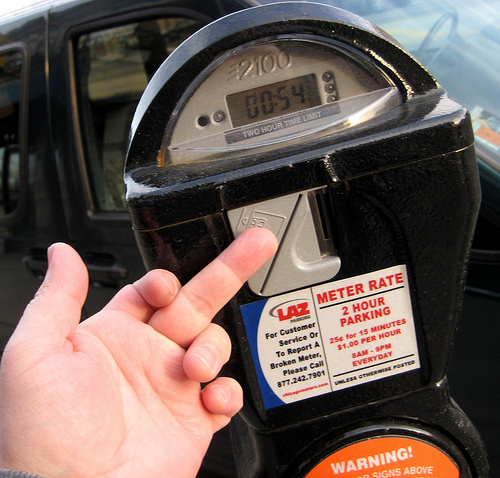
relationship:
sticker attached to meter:
[302, 434, 461, 477] [121, 0, 489, 477]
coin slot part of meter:
[258, 193, 304, 298] [121, 0, 489, 477]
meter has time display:
[121, 0, 489, 477] [224, 72, 330, 131]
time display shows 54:
[224, 72, 330, 131] [273, 81, 306, 111]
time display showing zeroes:
[224, 72, 330, 131] [245, 90, 275, 119]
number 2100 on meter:
[235, 48, 291, 81] [121, 0, 489, 477]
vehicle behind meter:
[1, 0, 499, 477] [121, 0, 489, 477]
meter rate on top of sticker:
[314, 272, 403, 305] [237, 263, 423, 411]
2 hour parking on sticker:
[340, 297, 391, 328] [237, 263, 423, 411]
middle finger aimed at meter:
[147, 226, 279, 353] [121, 0, 489, 477]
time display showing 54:
[224, 72, 330, 131] [273, 81, 306, 111]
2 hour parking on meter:
[340, 297, 391, 328] [121, 0, 489, 477]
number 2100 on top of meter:
[235, 48, 291, 81] [121, 0, 489, 477]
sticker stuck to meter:
[302, 434, 461, 477] [121, 0, 489, 477]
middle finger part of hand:
[147, 226, 279, 353] [0, 227, 280, 477]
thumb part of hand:
[3, 242, 90, 361] [0, 227, 280, 477]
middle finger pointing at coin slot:
[147, 226, 279, 353] [258, 193, 304, 298]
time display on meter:
[224, 72, 330, 131] [121, 0, 489, 477]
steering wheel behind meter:
[412, 8, 458, 72] [121, 0, 489, 477]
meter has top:
[121, 0, 489, 477] [113, 0, 445, 170]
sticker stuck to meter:
[237, 263, 423, 411] [121, 0, 489, 477]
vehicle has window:
[1, 0, 499, 477] [58, 7, 219, 214]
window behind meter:
[58, 7, 219, 214] [121, 0, 489, 477]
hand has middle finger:
[0, 227, 280, 477] [147, 226, 279, 353]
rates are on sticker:
[328, 316, 415, 353] [237, 263, 423, 411]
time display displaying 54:
[224, 72, 330, 131] [273, 81, 306, 111]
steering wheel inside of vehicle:
[412, 8, 458, 72] [1, 0, 499, 477]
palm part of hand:
[0, 312, 210, 477] [0, 227, 280, 477]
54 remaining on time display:
[273, 81, 306, 111] [224, 72, 330, 131]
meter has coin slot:
[121, 0, 489, 477] [258, 193, 304, 298]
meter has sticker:
[121, 0, 489, 477] [302, 434, 461, 477]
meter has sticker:
[121, 0, 489, 477] [237, 263, 423, 411]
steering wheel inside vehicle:
[412, 8, 458, 72] [1, 0, 499, 477]